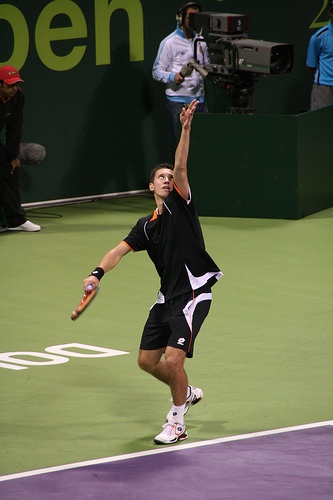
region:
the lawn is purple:
[195, 460, 230, 489]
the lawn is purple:
[214, 474, 223, 494]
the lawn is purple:
[214, 464, 229, 493]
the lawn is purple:
[216, 474, 238, 494]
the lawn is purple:
[229, 460, 251, 494]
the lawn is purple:
[230, 477, 250, 496]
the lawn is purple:
[217, 459, 243, 488]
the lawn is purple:
[221, 485, 241, 498]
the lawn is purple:
[251, 433, 271, 474]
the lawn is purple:
[233, 481, 264, 497]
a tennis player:
[59, 93, 222, 460]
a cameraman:
[164, 6, 280, 105]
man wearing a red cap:
[2, 61, 32, 87]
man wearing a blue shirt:
[305, 24, 332, 82]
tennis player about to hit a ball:
[51, 91, 235, 328]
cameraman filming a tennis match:
[157, 4, 290, 109]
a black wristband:
[88, 262, 107, 281]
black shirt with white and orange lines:
[123, 192, 220, 270]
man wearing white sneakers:
[157, 385, 222, 453]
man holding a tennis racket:
[63, 235, 123, 320]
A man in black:
[114, 180, 221, 401]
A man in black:
[151, 210, 214, 384]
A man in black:
[135, 279, 179, 443]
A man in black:
[130, 155, 203, 331]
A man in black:
[153, 234, 220, 499]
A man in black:
[111, 213, 291, 428]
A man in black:
[174, 309, 204, 370]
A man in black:
[159, 241, 176, 304]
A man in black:
[159, 320, 192, 378]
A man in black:
[182, 245, 184, 300]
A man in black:
[155, 247, 189, 319]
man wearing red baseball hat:
[2, 67, 33, 238]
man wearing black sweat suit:
[2, 64, 40, 239]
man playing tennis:
[52, 84, 236, 445]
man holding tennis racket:
[62, 81, 246, 459]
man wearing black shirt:
[59, 96, 229, 445]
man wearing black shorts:
[68, 88, 241, 447]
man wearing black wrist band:
[52, 85, 255, 445]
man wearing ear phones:
[156, 1, 233, 181]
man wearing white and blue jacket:
[155, 4, 212, 168]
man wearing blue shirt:
[306, 8, 330, 129]